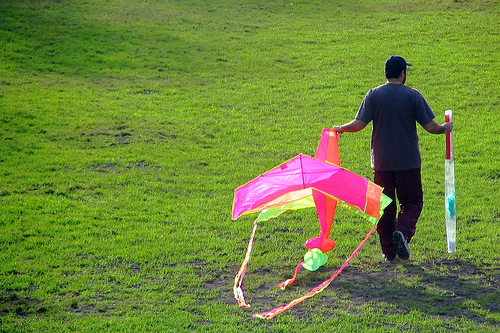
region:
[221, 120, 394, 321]
Colorful kite dragging the ground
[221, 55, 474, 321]
Man dragging a kite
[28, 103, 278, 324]
Green patchy grass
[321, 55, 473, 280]
Man walking through a field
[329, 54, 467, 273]
Man in cap and sneakers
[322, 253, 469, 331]
Shadow of a kite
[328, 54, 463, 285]
Man carrying a kite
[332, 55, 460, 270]
Man in a t-shirt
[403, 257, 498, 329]
Shadow of a man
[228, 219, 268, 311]
Tassel of a kite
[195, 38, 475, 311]
this guy is flying a kite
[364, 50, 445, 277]
he is wearing black pants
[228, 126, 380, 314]
this kite is colorful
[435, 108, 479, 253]
he is holding something in his hand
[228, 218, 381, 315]
the tails on this kite are pink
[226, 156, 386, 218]
the wings on this kite are pink and orange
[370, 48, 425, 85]
the man's baseball cap is black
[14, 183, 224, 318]
this grass looks muddy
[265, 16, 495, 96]
the grass is very bright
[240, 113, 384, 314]
this man is carrying his kite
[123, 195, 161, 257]
part of a field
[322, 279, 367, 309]
part of a ribbon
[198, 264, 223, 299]
part of a ground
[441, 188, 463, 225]
part of a plastic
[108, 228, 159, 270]
part of a ground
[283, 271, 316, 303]
part of a ribbon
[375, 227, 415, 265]
part of a sole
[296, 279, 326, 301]
part of a ribbon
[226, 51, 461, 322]
a man with a kite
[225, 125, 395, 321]
the kite is pink and green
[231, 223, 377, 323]
the tail of the kite is pink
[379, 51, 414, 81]
the man is wearing a hat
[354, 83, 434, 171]
the man's shirt is blue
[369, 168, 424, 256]
the man's pants are dark colored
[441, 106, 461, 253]
a long piece of plastic in the man's hand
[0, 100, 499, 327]
the grass has dirt patches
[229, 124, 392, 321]
the kite is shaped like an airplane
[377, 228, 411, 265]
the man is wearing sneakers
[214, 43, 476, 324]
a man and his kite in a park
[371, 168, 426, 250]
the man has maroon pants on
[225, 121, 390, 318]
the kite is pink and orange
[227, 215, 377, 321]
the tails are pink and yellow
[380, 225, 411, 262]
the man has sneakers on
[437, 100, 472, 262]
a folded up kite is in his hand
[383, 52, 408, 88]
the man has dark hair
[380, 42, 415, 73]
the man has a dark cap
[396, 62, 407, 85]
a beard is on the man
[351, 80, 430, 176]
the person is wearing a gray t-shirt